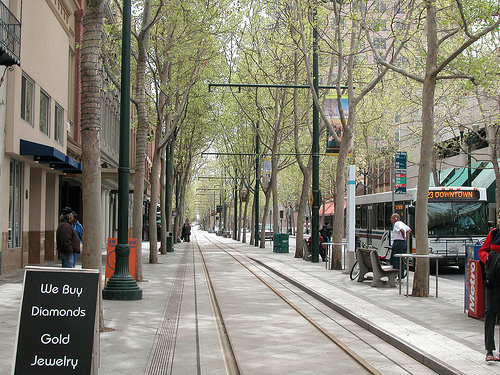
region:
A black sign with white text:
[10, 263, 100, 373]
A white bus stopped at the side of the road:
[343, 185, 488, 270]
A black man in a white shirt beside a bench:
[385, 211, 412, 281]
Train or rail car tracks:
[146, 220, 461, 374]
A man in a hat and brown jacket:
[54, 205, 84, 266]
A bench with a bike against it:
[355, 245, 399, 286]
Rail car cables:
[185, 81, 344, 204]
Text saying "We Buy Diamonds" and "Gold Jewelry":
[30, 283, 86, 370]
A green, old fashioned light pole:
[102, 0, 143, 300]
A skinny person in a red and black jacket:
[477, 210, 499, 363]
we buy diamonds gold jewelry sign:
[15, 265, 90, 373]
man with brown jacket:
[55, 205, 78, 266]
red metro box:
[465, 258, 484, 317]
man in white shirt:
[389, 212, 408, 273]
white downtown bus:
[359, 185, 488, 266]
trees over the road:
[162, 7, 294, 179]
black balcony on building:
[2, 2, 22, 64]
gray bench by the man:
[359, 245, 394, 288]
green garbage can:
[269, 230, 291, 255]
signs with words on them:
[394, 150, 409, 196]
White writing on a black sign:
[15, 259, 104, 371]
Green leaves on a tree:
[192, 86, 220, 143]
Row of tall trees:
[222, 1, 497, 298]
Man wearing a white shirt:
[381, 208, 411, 272]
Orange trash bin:
[97, 232, 145, 286]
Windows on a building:
[9, 66, 72, 150]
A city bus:
[332, 180, 493, 280]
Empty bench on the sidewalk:
[351, 239, 400, 292]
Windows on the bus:
[342, 191, 407, 233]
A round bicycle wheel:
[345, 253, 364, 286]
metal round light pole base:
[102, 241, 143, 301]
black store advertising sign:
[14, 264, 103, 373]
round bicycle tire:
[348, 257, 358, 279]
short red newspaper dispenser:
[466, 256, 484, 315]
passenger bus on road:
[333, 185, 490, 271]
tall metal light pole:
[115, 3, 135, 240]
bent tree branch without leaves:
[362, 25, 424, 83]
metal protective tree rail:
[393, 251, 443, 297]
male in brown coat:
[56, 204, 81, 266]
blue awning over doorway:
[18, 135, 67, 169]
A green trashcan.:
[267, 231, 291, 256]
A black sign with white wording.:
[14, 262, 97, 370]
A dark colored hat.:
[59, 205, 78, 214]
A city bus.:
[327, 185, 498, 270]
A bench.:
[353, 241, 399, 291]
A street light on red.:
[206, 207, 216, 217]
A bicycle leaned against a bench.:
[349, 240, 410, 285]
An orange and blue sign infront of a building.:
[104, 235, 139, 290]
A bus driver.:
[454, 208, 479, 233]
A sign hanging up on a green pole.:
[301, 20, 359, 260]